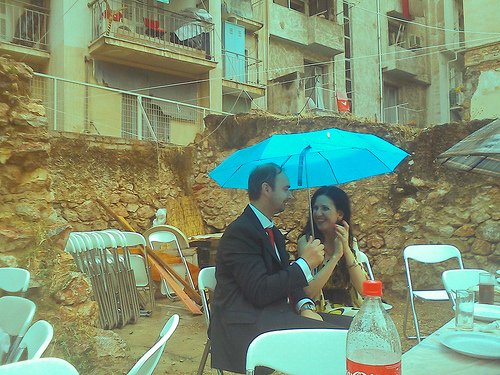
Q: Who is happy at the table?
A: Male and female.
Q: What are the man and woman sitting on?
A: Chairs.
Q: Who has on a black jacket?
A: The man.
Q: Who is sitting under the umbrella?
A: Lady and man.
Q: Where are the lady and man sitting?
A: In chairs.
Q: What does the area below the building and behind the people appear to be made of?
A: Stone.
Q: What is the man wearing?
A: A suit.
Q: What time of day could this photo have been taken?
A: Afternoon.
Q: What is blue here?
A: Umbrella.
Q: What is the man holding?
A: An umbrella.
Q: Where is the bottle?
A: On the table.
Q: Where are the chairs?
A: On the ground.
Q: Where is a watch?
A: Man's wrist.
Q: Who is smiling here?
A: The lady.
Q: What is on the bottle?
A: A cap.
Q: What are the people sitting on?
A: Chairs.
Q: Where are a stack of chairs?
A: Between the rocks.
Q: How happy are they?
A: Very happy.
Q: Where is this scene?
A: Outdoor dining.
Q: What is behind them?
A: Housing.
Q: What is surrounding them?
A: Stones.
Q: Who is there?
A: Couple.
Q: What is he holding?
A: Umbrella.